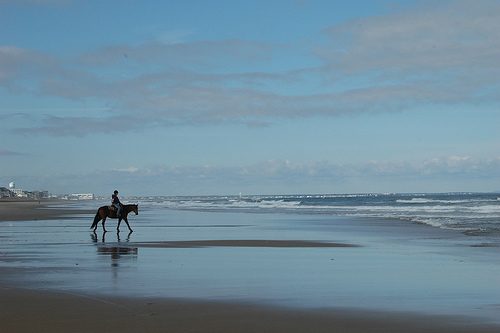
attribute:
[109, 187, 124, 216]
person — riding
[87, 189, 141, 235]
person horse — riding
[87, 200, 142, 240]
horse — walking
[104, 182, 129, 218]
someone — riding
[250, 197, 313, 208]
waves — big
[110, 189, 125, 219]
someone — riding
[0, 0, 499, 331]
beach — dark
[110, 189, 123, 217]
person — enjoying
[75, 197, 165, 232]
jeans — blue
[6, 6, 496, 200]
sky — blue 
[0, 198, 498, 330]
sand — reflecting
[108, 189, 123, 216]
someone — enjoying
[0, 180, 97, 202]
buildings — background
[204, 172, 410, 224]
bridge — distant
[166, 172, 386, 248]
water — choppy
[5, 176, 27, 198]
tank — large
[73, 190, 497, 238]
water — blue, sea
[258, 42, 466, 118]
clouds — white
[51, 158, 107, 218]
building — white